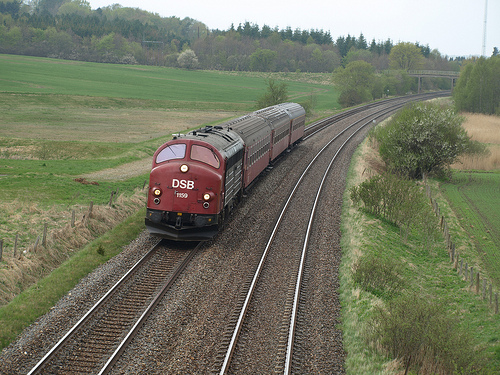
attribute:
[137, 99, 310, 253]
train — red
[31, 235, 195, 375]
track — empty, present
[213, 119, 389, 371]
track — empty, present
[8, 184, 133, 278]
fence — wire, wooden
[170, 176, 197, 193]
letters — white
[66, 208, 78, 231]
post — wooden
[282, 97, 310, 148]
car — last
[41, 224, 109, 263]
grass — dry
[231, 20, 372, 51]
trees — deciduous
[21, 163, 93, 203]
grass — green